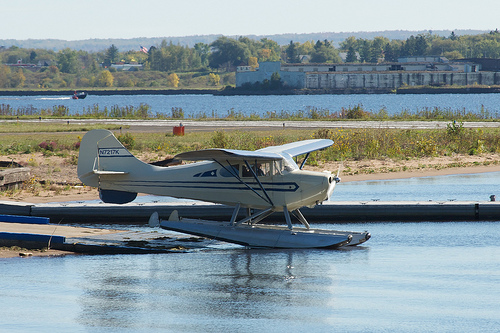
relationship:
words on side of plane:
[93, 140, 135, 169] [68, 105, 388, 265]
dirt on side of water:
[0, 149, 498, 203] [0, 166, 500, 331]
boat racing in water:
[73, 93, 88, 100] [2, 93, 499, 114]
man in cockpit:
[249, 160, 264, 178] [240, 160, 287, 178]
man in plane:
[249, 160, 264, 178] [71, 125, 373, 253]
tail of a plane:
[41, 128, 139, 195] [71, 125, 373, 253]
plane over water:
[23, 103, 373, 290] [218, 249, 450, 309]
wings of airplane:
[169, 131, 337, 159] [78, 116, 371, 253]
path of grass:
[0, 115, 497, 132] [0, 132, 498, 154]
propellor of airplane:
[322, 154, 346, 194] [78, 116, 371, 253]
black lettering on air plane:
[94, 145, 132, 160] [65, 119, 380, 259]